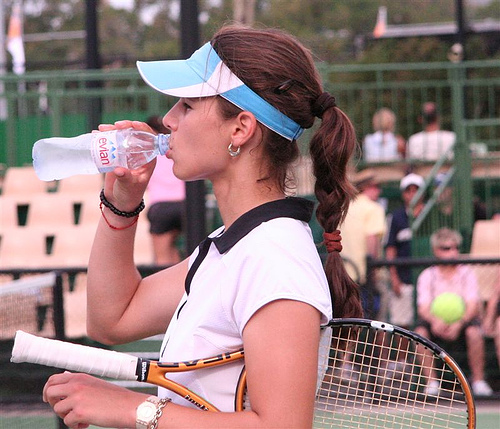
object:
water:
[33, 139, 160, 181]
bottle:
[31, 128, 172, 182]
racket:
[10, 329, 476, 428]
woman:
[40, 25, 333, 429]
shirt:
[154, 196, 334, 409]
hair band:
[312, 92, 337, 119]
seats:
[1, 155, 183, 271]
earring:
[228, 143, 241, 156]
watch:
[135, 395, 163, 428]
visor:
[136, 41, 307, 143]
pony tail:
[310, 106, 365, 355]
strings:
[240, 327, 466, 428]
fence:
[1, 57, 497, 293]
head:
[163, 28, 323, 181]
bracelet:
[150, 397, 172, 429]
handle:
[10, 330, 137, 382]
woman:
[413, 226, 495, 396]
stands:
[1, 153, 495, 396]